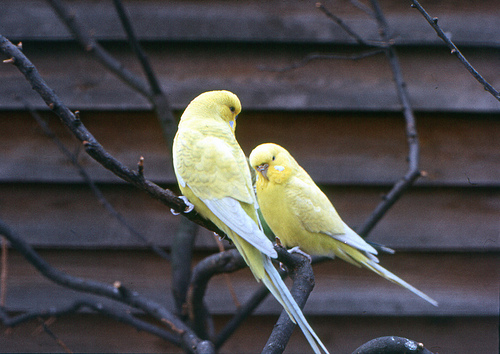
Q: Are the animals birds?
A: Yes, all the animals are birds.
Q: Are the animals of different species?
A: No, all the animals are birds.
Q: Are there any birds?
A: Yes, there are birds.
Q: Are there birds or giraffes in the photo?
A: Yes, there are birds.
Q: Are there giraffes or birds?
A: Yes, there are birds.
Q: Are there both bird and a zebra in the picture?
A: No, there are birds but no zebras.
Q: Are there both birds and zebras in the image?
A: No, there are birds but no zebras.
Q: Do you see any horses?
A: No, there are no horses.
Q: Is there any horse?
A: No, there are no horses.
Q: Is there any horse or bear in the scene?
A: No, there are no horses or bears.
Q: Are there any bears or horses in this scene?
A: No, there are no horses or bears.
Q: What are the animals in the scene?
A: The animals are birds.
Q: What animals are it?
A: The animals are birds.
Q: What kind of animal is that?
A: These are birds.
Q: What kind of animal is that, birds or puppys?
A: These are birds.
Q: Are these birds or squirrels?
A: These are birds.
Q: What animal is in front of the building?
A: The birds are in front of the building.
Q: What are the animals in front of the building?
A: The animals are birds.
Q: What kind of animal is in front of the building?
A: The animals are birds.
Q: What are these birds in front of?
A: The birds are in front of the building.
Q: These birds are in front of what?
A: The birds are in front of the building.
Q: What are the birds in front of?
A: The birds are in front of the building.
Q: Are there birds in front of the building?
A: Yes, there are birds in front of the building.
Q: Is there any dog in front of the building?
A: No, there are birds in front of the building.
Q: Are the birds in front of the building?
A: Yes, the birds are in front of the building.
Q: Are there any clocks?
A: No, there are no clocks.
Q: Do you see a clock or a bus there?
A: No, there are no clocks or buses.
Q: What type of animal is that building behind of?
A: The building is behind the birds.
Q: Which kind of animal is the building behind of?
A: The building is behind the birds.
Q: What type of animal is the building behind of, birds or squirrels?
A: The building is behind birds.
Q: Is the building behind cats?
A: No, the building is behind the birds.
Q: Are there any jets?
A: No, there are no jets.